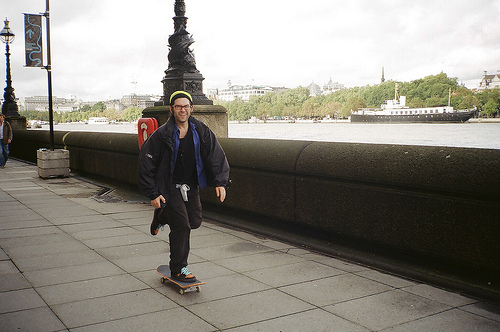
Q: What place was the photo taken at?
A: It was taken at the walkway.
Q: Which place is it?
A: It is a walkway.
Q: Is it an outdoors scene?
A: Yes, it is outdoors.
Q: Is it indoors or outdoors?
A: It is outdoors.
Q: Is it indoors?
A: No, it is outdoors.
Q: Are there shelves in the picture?
A: No, there are no shelves.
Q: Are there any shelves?
A: No, there are no shelves.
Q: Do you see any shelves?
A: No, there are no shelves.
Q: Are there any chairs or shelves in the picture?
A: No, there are no shelves or chairs.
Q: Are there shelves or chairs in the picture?
A: No, there are no shelves or chairs.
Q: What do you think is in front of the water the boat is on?
A: The wall is in front of the water.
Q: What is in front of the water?
A: The wall is in front of the water.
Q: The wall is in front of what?
A: The wall is in front of the water.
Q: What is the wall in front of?
A: The wall is in front of the water.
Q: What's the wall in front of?
A: The wall is in front of the water.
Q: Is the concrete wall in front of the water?
A: Yes, the wall is in front of the water.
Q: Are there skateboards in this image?
A: Yes, there is a skateboard.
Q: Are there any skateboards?
A: Yes, there is a skateboard.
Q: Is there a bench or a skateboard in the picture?
A: Yes, there is a skateboard.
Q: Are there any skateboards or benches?
A: Yes, there is a skateboard.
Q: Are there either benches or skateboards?
A: Yes, there is a skateboard.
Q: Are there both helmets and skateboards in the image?
A: No, there is a skateboard but no helmets.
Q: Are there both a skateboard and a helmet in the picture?
A: No, there is a skateboard but no helmets.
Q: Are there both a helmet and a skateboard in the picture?
A: No, there is a skateboard but no helmets.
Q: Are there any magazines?
A: No, there are no magazines.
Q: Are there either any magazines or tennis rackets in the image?
A: No, there are no magazines or tennis rackets.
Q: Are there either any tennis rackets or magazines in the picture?
A: No, there are no magazines or tennis rackets.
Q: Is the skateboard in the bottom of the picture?
A: Yes, the skateboard is in the bottom of the image.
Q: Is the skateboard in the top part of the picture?
A: No, the skateboard is in the bottom of the image.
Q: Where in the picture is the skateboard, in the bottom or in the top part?
A: The skateboard is in the bottom of the image.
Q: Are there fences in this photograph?
A: No, there are no fences.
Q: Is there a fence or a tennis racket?
A: No, there are no fences or rackets.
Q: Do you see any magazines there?
A: No, there are no magazines.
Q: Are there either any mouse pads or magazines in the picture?
A: No, there are no magazines or mouse pads.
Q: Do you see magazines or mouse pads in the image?
A: No, there are no magazines or mouse pads.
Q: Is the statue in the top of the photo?
A: Yes, the statue is in the top of the image.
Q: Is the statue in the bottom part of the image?
A: No, the statue is in the top of the image.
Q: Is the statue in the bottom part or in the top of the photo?
A: The statue is in the top of the image.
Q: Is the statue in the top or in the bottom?
A: The statue is in the top of the image.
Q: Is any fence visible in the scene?
A: No, there are no fences.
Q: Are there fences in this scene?
A: No, there are no fences.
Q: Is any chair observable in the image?
A: No, there are no chairs.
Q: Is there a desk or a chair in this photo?
A: No, there are no chairs or desks.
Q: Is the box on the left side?
A: Yes, the box is on the left of the image.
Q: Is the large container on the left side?
A: Yes, the box is on the left of the image.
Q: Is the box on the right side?
A: No, the box is on the left of the image.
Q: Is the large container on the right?
A: No, the box is on the left of the image.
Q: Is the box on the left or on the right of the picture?
A: The box is on the left of the image.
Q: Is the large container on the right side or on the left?
A: The box is on the left of the image.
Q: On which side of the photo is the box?
A: The box is on the left of the image.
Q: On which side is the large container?
A: The box is on the left of the image.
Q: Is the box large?
A: Yes, the box is large.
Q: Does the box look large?
A: Yes, the box is large.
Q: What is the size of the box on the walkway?
A: The box is large.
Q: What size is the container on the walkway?
A: The box is large.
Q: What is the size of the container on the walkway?
A: The box is large.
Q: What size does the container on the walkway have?
A: The box has large size.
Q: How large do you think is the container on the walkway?
A: The box is large.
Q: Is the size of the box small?
A: No, the box is large.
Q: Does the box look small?
A: No, the box is large.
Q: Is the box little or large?
A: The box is large.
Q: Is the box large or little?
A: The box is large.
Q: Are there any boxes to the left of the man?
A: Yes, there is a box to the left of the man.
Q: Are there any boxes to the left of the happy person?
A: Yes, there is a box to the left of the man.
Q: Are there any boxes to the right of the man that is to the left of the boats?
A: No, the box is to the left of the man.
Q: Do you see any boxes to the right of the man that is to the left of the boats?
A: No, the box is to the left of the man.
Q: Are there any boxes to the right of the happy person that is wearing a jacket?
A: No, the box is to the left of the man.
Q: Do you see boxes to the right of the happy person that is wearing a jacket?
A: No, the box is to the left of the man.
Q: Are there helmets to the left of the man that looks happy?
A: No, there is a box to the left of the man.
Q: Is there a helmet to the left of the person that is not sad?
A: No, there is a box to the left of the man.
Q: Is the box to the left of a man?
A: Yes, the box is to the left of a man.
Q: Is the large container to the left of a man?
A: Yes, the box is to the left of a man.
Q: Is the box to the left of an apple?
A: No, the box is to the left of a man.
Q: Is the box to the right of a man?
A: No, the box is to the left of a man.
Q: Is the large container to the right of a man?
A: No, the box is to the left of a man.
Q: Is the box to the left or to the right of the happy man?
A: The box is to the left of the man.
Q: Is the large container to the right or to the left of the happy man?
A: The box is to the left of the man.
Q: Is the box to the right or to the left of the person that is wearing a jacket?
A: The box is to the left of the man.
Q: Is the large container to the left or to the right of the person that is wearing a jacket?
A: The box is to the left of the man.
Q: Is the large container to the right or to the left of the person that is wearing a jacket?
A: The box is to the left of the man.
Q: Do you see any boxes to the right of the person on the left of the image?
A: Yes, there is a box to the right of the person.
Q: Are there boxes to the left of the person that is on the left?
A: No, the box is to the right of the person.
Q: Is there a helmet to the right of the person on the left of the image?
A: No, there is a box to the right of the person.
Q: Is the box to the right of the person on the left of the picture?
A: Yes, the box is to the right of the person.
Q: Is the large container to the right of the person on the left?
A: Yes, the box is to the right of the person.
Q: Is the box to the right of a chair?
A: No, the box is to the right of the person.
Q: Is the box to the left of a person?
A: No, the box is to the right of a person.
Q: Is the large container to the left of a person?
A: No, the box is to the right of a person.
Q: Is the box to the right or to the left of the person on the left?
A: The box is to the right of the person.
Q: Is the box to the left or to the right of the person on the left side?
A: The box is to the right of the person.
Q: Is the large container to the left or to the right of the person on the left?
A: The box is to the right of the person.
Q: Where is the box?
A: The box is on the walkway.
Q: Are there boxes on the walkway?
A: Yes, there is a box on the walkway.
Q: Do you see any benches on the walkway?
A: No, there is a box on the walkway.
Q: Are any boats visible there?
A: Yes, there is a boat.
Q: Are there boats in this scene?
A: Yes, there is a boat.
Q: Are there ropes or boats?
A: Yes, there is a boat.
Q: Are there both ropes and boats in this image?
A: No, there is a boat but no ropes.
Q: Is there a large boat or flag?
A: Yes, there is a large boat.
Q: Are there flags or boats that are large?
A: Yes, the boat is large.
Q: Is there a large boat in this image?
A: Yes, there is a large boat.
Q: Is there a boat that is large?
A: Yes, there is a boat that is large.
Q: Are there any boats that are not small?
A: Yes, there is a large boat.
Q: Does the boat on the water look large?
A: Yes, the boat is large.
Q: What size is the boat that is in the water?
A: The boat is large.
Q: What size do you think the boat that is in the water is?
A: The boat is large.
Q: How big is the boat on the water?
A: The boat is large.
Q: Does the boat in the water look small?
A: No, the boat is large.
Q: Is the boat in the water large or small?
A: The boat is large.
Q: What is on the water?
A: The boat is on the water.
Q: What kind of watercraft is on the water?
A: The watercraft is a boat.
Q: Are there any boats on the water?
A: Yes, there is a boat on the water.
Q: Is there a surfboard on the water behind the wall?
A: No, there is a boat on the water.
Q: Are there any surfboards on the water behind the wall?
A: No, there is a boat on the water.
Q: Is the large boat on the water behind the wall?
A: Yes, the boat is on the water.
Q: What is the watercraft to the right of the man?
A: The watercraft is a boat.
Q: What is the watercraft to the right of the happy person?
A: The watercraft is a boat.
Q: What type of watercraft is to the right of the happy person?
A: The watercraft is a boat.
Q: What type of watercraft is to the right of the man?
A: The watercraft is a boat.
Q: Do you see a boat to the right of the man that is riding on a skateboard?
A: Yes, there is a boat to the right of the man.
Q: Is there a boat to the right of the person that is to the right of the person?
A: Yes, there is a boat to the right of the man.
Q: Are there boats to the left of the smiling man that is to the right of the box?
A: No, the boat is to the right of the man.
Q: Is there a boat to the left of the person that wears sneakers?
A: No, the boat is to the right of the man.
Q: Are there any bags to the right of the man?
A: No, there is a boat to the right of the man.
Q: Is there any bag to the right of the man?
A: No, there is a boat to the right of the man.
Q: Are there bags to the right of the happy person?
A: No, there is a boat to the right of the man.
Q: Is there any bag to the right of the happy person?
A: No, there is a boat to the right of the man.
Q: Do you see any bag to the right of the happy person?
A: No, there is a boat to the right of the man.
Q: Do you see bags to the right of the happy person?
A: No, there is a boat to the right of the man.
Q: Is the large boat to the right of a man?
A: Yes, the boat is to the right of a man.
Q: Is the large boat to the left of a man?
A: No, the boat is to the right of a man.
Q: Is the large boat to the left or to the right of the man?
A: The boat is to the right of the man.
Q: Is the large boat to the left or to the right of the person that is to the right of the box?
A: The boat is to the right of the man.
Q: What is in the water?
A: The boat is in the water.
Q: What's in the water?
A: The boat is in the water.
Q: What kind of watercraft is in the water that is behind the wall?
A: The watercraft is a boat.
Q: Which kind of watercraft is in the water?
A: The watercraft is a boat.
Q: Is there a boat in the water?
A: Yes, there is a boat in the water.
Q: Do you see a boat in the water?
A: Yes, there is a boat in the water.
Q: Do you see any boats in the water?
A: Yes, there is a boat in the water.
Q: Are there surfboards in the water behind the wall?
A: No, there is a boat in the water.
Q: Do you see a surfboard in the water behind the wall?
A: No, there is a boat in the water.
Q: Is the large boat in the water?
A: Yes, the boat is in the water.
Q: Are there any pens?
A: No, there are no pens.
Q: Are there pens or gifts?
A: No, there are no pens or gifts.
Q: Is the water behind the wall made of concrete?
A: Yes, the water is behind the wall.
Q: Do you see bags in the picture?
A: No, there are no bags.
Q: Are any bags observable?
A: No, there are no bags.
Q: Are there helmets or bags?
A: No, there are no bags or helmets.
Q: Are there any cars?
A: No, there are no cars.